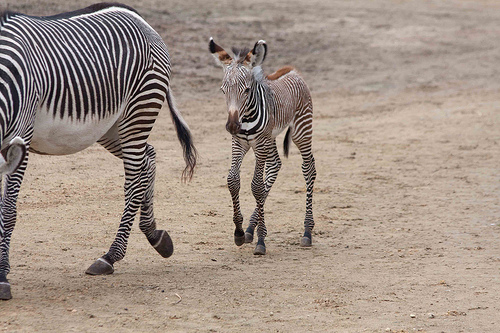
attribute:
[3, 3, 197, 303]
zebra — adult,  large zebra's , leading, in front of baby, walking,  striped, big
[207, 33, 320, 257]
baby zebra — standing up, on ground, small, behind mom, walking, following, young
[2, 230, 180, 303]
hooves — hard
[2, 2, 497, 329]
ground — sandy, bare, dry, dirt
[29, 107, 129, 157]
belly — white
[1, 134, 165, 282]
legs — striped , adult zebra 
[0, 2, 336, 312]
zebras — running, black, white